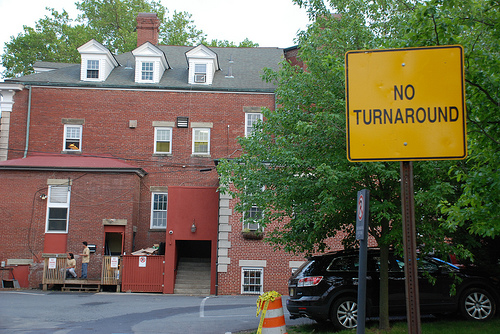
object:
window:
[240, 268, 261, 294]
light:
[176, 116, 189, 128]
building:
[3, 10, 413, 317]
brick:
[87, 125, 102, 136]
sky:
[0, 1, 324, 45]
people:
[77, 240, 92, 280]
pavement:
[0, 292, 307, 332]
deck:
[38, 253, 121, 293]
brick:
[85, 126, 96, 131]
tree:
[217, 0, 484, 331]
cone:
[257, 290, 292, 333]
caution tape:
[256, 291, 285, 334]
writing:
[354, 224, 364, 238]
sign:
[356, 189, 366, 241]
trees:
[0, 0, 219, 76]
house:
[2, 12, 442, 297]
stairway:
[174, 242, 216, 297]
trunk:
[373, 228, 395, 328]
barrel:
[250, 289, 290, 334]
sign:
[346, 46, 465, 163]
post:
[399, 160, 422, 333]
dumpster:
[120, 254, 164, 293]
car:
[287, 245, 497, 329]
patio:
[40, 252, 117, 286]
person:
[64, 252, 77, 279]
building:
[0, 12, 450, 296]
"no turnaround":
[353, 84, 463, 124]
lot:
[4, 288, 304, 332]